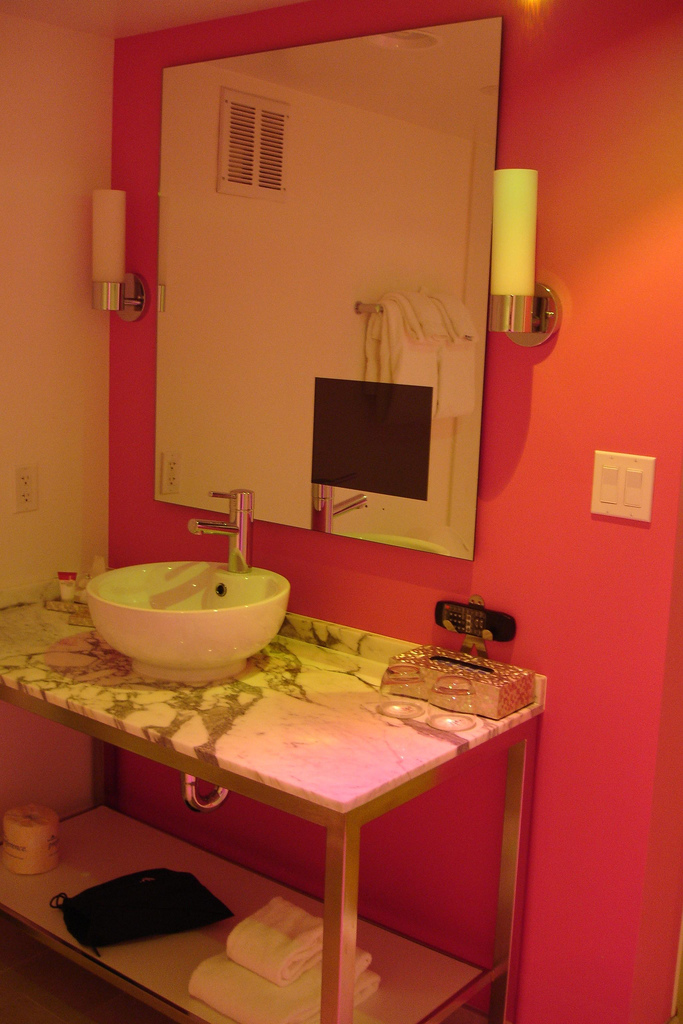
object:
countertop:
[0, 576, 548, 815]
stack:
[187, 896, 380, 1024]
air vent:
[216, 86, 291, 204]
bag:
[50, 867, 235, 957]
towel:
[226, 895, 323, 987]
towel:
[189, 947, 381, 1022]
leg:
[320, 827, 360, 1022]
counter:
[0, 579, 546, 1024]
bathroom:
[0, 0, 683, 1024]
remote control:
[434, 600, 516, 642]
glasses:
[379, 663, 477, 732]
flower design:
[388, 644, 535, 720]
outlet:
[13, 462, 38, 514]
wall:
[0, 11, 116, 954]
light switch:
[591, 450, 656, 523]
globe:
[92, 189, 127, 283]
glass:
[379, 663, 426, 719]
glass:
[426, 674, 477, 732]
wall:
[106, 0, 683, 1024]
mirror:
[153, 15, 501, 563]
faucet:
[188, 489, 255, 575]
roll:
[3, 804, 61, 875]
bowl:
[85, 561, 290, 682]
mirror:
[311, 377, 434, 502]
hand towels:
[365, 285, 479, 419]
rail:
[354, 301, 384, 315]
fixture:
[92, 189, 150, 322]